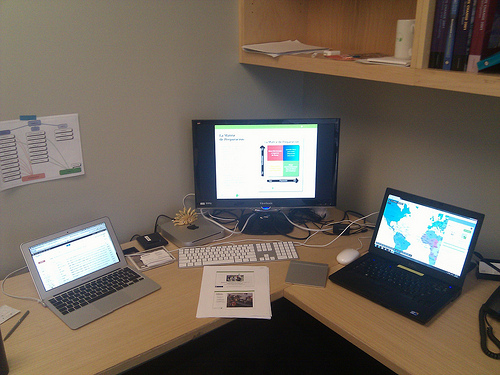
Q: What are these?
A: Laptops.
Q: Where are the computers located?
A: On the desk.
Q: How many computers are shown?
A: Three.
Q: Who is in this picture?
A: No one.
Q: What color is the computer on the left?
A: Silver.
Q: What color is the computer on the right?
A: Black.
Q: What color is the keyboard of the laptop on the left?
A: Black.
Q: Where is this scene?
A: Inside of an office.